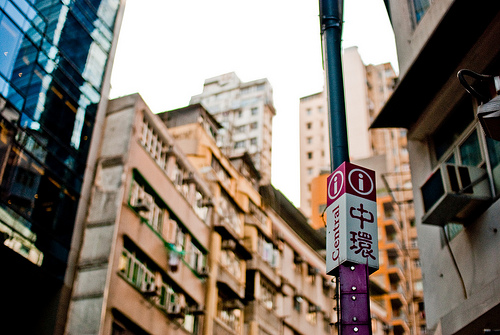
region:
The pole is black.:
[316, 20, 352, 160]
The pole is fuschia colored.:
[332, 260, 374, 332]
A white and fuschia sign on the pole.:
[323, 160, 381, 270]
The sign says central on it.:
[325, 202, 345, 262]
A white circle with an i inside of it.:
[347, 163, 374, 196]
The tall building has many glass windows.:
[0, 0, 130, 331]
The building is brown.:
[83, 86, 414, 332]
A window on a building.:
[418, 88, 489, 255]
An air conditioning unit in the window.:
[411, 143, 493, 233]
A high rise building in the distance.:
[181, 47, 284, 172]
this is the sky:
[148, 6, 229, 47]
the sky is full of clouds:
[175, 16, 274, 47]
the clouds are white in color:
[165, 13, 249, 62]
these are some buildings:
[11, 14, 498, 320]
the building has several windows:
[137, 186, 277, 303]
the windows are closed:
[149, 208, 169, 228]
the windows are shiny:
[16, 23, 90, 103]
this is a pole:
[312, 0, 390, 329]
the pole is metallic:
[328, 109, 347, 165]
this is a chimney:
[415, 159, 451, 211]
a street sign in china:
[280, 128, 427, 290]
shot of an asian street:
[64, 28, 476, 298]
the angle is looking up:
[42, 55, 484, 315]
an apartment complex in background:
[122, 91, 316, 333]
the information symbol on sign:
[338, 162, 396, 207]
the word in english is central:
[320, 158, 367, 262]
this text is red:
[322, 191, 379, 266]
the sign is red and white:
[292, 131, 464, 333]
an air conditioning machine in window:
[402, 79, 486, 220]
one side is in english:
[301, 139, 456, 303]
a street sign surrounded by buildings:
[307, 2, 384, 332]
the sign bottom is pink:
[330, 262, 373, 331]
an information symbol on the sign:
[326, 157, 377, 206]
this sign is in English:
[325, 191, 348, 271]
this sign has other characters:
[342, 189, 378, 267]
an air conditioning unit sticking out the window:
[417, 86, 488, 230]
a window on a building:
[414, 87, 498, 237]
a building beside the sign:
[372, 0, 494, 330]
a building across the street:
[64, 89, 341, 332]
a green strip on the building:
[120, 195, 207, 287]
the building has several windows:
[139, 151, 202, 331]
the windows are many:
[137, 141, 214, 331]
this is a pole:
[319, 12, 354, 153]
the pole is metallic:
[326, 37, 348, 163]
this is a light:
[459, 67, 499, 124]